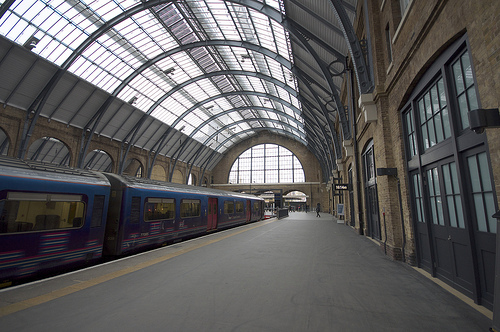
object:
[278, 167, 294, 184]
window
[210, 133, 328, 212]
terminal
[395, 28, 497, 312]
doors